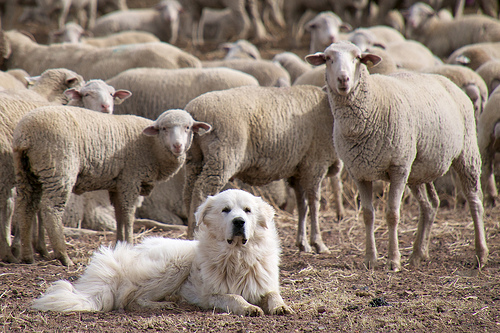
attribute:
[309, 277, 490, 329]
grass — brown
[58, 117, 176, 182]
wool — white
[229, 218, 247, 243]
nose — black 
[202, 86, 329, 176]
sheep — white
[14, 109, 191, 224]
sheep — white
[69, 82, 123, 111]
sheep — white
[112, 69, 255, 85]
sheep — white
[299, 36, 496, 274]
sheep — white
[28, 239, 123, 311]
dog's tail — furry, white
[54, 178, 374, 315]
dog — big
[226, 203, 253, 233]
nose — black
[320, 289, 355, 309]
grass — cut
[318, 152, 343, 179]
wool — rugged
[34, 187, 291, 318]
dog — white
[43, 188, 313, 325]
dog — white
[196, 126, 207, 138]
tag — white